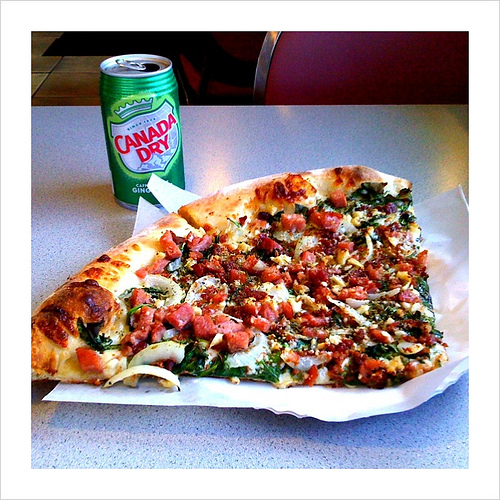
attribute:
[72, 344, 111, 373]
tomato — red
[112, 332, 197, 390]
onion — white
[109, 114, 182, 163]
canada dry — written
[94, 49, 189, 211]
can — ginger ale, canada dry, green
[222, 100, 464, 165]
reflection — light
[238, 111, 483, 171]
table — black and white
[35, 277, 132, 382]
crust section — burnt, raised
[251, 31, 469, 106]
chair — red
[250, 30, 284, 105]
frame — silver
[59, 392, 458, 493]
table — dark, speckled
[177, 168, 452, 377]
pizza slice — large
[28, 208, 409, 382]
pizza slice — large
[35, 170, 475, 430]
paper — white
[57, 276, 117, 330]
bubble — dark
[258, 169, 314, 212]
bubble — dark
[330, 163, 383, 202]
bubble — dark